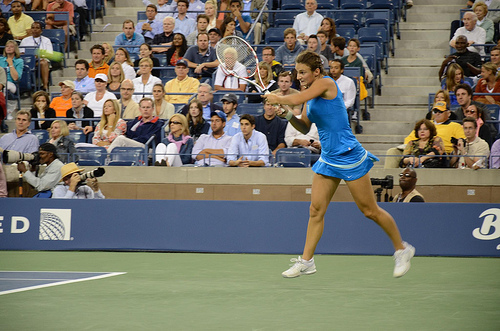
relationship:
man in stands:
[226, 114, 270, 169] [66, 12, 306, 161]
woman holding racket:
[259, 51, 416, 278] [215, 33, 287, 113]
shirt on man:
[50, 86, 77, 118] [43, 78, 81, 119]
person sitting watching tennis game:
[122, 57, 164, 102] [23, 43, 499, 329]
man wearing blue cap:
[190, 105, 237, 165] [208, 103, 229, 122]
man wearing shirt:
[136, 82, 274, 185] [294, 82, 430, 177]